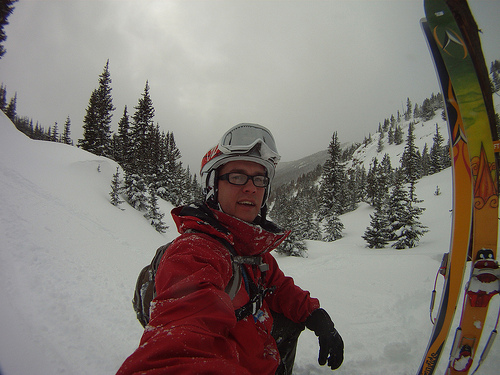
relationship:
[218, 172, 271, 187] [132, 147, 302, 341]
glasses on man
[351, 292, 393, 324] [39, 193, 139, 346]
tracks in snow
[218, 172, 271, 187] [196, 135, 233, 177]
glasses on helmet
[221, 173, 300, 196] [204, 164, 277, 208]
glasses on face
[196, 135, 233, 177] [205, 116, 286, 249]
helmet on head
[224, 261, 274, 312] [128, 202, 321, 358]
straps on coat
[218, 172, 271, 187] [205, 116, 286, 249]
glasses on head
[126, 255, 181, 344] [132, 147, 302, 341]
backpack on man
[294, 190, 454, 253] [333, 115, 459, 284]
trees on mountainside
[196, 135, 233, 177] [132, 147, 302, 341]
helmet on man